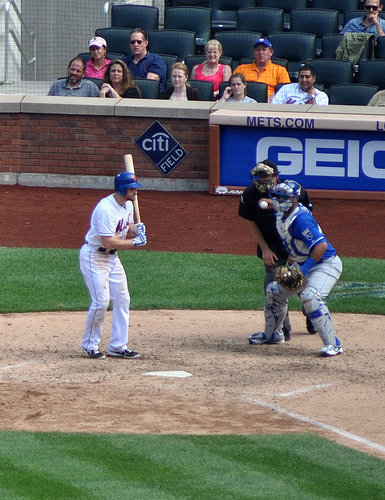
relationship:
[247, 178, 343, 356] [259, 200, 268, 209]
catcher throwing ball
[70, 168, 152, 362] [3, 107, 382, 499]
person in ball game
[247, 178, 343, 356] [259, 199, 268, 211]
catcher holding ball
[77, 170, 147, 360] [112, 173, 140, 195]
batter has helmet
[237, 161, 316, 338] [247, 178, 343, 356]
umpire standing behind catcher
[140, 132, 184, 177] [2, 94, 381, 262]
citifield on wall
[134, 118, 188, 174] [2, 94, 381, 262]
sign on wall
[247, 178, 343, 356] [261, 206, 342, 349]
catcher has uniform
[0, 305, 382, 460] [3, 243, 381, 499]
dirt on field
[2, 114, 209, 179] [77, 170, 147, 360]
brick behind batter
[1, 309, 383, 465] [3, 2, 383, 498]
track in photo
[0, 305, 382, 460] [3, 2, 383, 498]
dirt in photo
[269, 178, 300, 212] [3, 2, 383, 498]
helmet in photo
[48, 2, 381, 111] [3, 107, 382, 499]
people watching ball game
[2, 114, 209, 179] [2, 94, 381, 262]
brick on wall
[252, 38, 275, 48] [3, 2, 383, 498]
cap in photo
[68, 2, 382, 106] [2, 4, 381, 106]
seats at stadium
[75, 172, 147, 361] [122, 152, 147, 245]
man carrying baseball bat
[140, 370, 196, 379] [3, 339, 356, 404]
home plate on a baseball diamond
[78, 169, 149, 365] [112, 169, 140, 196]
ball player has helmet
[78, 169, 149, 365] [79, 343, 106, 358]
ball player has foot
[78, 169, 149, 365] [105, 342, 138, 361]
ball player has foot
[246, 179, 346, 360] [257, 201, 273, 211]
baseball catcher throwing a ball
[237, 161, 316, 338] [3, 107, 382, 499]
umpire in ball game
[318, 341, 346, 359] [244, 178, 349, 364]
foot on catcher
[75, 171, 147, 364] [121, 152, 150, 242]
player holding bat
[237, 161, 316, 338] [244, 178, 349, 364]
umpire behind catcher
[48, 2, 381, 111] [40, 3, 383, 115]
people watching from stands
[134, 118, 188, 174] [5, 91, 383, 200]
sign on wall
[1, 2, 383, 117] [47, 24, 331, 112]
netting in front of fans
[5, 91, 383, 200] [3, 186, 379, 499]
wall at edge of field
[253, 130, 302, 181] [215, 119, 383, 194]
letters on advertisement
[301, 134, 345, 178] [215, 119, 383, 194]
letters on advertisement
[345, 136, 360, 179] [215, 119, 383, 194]
letters on advertisement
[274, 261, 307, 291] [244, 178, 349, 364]
mitt on catcher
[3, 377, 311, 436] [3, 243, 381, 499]
mud on field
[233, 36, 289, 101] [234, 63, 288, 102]
man in shirt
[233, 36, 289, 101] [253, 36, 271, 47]
man in cap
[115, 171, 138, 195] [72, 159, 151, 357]
helmet on batter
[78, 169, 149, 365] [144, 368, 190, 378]
ball player standing at plate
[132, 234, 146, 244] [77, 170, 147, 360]
glove of batter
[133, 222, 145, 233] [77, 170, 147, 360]
glove of batter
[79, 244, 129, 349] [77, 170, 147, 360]
pants of batter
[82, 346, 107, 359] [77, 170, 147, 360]
shoe of batter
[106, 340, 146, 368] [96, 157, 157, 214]
shoe of batter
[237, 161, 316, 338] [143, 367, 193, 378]
umpire behind plate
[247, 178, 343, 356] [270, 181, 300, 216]
catcher wearing helmet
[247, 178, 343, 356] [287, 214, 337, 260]
catcher wearing jersey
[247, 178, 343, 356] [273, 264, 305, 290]
catcher wearing mitt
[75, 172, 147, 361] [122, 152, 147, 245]
man holding baseball bat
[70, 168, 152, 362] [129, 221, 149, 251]
person wearing gloves